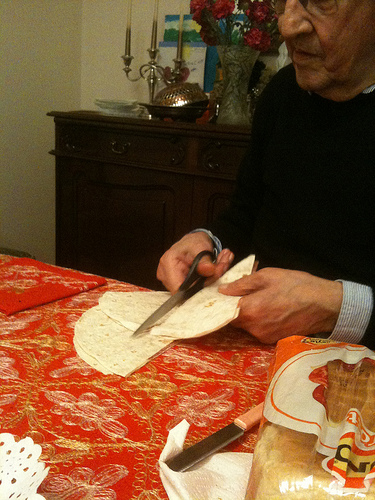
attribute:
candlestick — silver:
[122, 1, 134, 56]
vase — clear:
[219, 42, 257, 127]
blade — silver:
[164, 413, 248, 474]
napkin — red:
[49, 377, 144, 487]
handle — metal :
[105, 136, 138, 156]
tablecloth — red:
[1, 251, 372, 499]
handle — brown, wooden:
[233, 390, 265, 440]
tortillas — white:
[62, 268, 246, 371]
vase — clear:
[212, 41, 257, 125]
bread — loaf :
[238, 335, 373, 498]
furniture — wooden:
[21, 51, 284, 251]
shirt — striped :
[239, 87, 361, 282]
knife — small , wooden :
[190, 434, 230, 456]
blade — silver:
[128, 290, 181, 337]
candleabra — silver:
[105, 6, 220, 159]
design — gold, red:
[21, 371, 143, 468]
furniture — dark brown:
[45, 106, 253, 290]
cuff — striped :
[324, 274, 373, 355]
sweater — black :
[198, 61, 373, 344]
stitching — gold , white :
[3, 255, 283, 498]